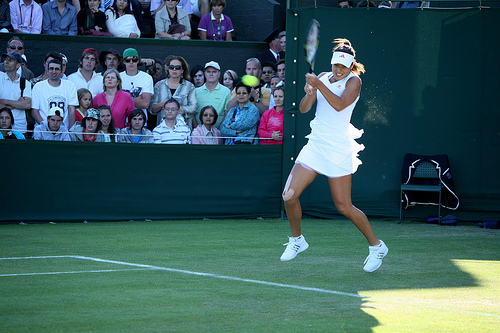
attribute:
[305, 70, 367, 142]
tennis top — white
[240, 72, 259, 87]
ball — yellow, tennis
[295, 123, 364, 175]
skirt — white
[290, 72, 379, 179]
dress — white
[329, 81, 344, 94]
symbol — red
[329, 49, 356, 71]
visor — white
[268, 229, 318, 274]
shoe — tennis, white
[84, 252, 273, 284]
line — white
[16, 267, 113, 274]
line — white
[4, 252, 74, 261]
line — white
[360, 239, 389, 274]
shoe — white, tennis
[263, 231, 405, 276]
tennis shoes — white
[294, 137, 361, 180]
skirt — white, tennis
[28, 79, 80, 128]
shirt — white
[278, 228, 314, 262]
shoe — white, tennis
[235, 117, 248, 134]
shirt — blue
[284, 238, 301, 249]
shoestrings — white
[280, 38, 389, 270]
player — tennis, female